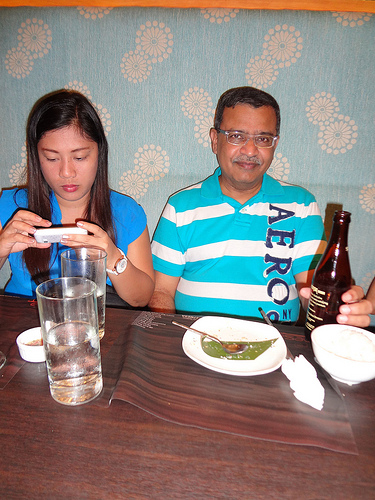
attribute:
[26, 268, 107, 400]
water — large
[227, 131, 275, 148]
glasses — plastic, with blue pieces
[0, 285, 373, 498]
table — dark colored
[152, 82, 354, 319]
man — seated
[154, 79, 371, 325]
man — seated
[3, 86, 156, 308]
woman — seated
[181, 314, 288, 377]
plate — white 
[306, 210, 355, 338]
glass bottle — tinted, mostly empty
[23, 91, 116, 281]
hair — long, straight, brown